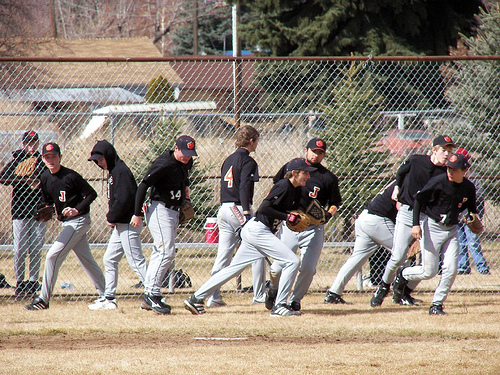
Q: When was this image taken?
A: During the day.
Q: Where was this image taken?
A: At a baseball field.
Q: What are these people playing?
A: Baseball.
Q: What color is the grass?
A: Yellow.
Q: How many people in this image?
A: 11.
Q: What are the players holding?
A: Baseball Mitts.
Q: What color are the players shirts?
A: Black.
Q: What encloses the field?
A: A fence.